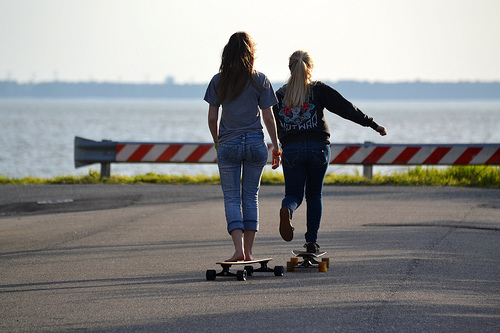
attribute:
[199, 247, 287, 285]
skateboard — wooden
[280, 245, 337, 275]
skateboard — black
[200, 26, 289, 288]
woman — skateboarding, standing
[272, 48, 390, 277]
woman — skateboarding, standing, blonde, pushing off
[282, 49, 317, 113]
ponytail — blonde, huge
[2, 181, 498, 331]
tar — black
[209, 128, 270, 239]
jeans — blue, rolled up, capri-length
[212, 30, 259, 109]
hair — brown, long, red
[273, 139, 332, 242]
jeans — blue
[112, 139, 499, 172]
stripes — red, white, orange, diagonal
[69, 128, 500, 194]
guardrail — orange, white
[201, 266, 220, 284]
wheel — black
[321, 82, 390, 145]
arm — extended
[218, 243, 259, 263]
feet — bare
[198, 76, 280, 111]
sleeves — short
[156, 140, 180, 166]
lines — red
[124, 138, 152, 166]
line — red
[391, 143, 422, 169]
line — red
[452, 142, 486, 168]
line — red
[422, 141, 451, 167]
line — red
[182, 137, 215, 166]
line — red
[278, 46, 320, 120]
hair — blonde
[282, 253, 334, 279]
wheels — yellow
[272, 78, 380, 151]
shirt — black